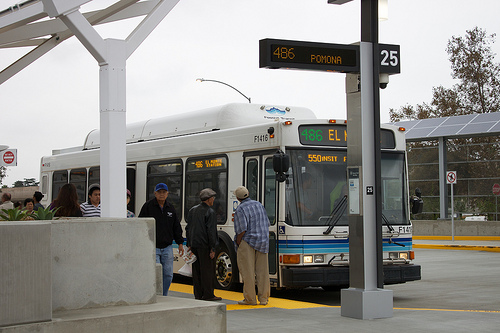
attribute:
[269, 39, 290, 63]
486 — green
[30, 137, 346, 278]
bus — large, blue, white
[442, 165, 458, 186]
sign — red, electric, digital, do not walk, stop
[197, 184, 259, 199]
hats — blue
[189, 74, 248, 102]
streetlight — here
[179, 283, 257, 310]
line — blue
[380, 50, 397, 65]
numbers — green, yellow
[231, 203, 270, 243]
shirt — stripes, blue, striped, checkered, plaid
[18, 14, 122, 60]
roof — grey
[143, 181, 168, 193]
hat — grey, blue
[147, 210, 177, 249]
jacket — black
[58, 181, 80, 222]
hair — brown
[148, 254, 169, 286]
jeans — blue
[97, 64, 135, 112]
pillar — white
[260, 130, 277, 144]
light cover — orange